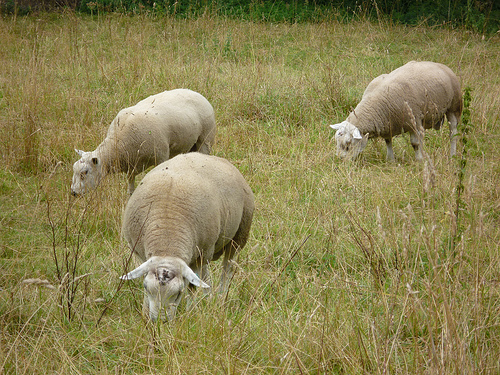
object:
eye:
[81, 170, 88, 179]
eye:
[174, 291, 181, 301]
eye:
[143, 284, 147, 292]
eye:
[344, 146, 350, 151]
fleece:
[142, 172, 206, 257]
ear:
[181, 264, 209, 288]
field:
[0, 0, 500, 375]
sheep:
[118, 151, 255, 325]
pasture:
[0, 15, 500, 375]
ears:
[119, 256, 211, 288]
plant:
[450, 86, 475, 264]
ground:
[0, 11, 500, 375]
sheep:
[68, 60, 463, 324]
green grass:
[0, 0, 500, 33]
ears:
[329, 122, 363, 139]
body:
[107, 88, 208, 144]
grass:
[0, 0, 500, 375]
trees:
[0, 0, 500, 35]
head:
[118, 255, 210, 323]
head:
[70, 148, 101, 197]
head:
[328, 122, 364, 158]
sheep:
[328, 60, 461, 165]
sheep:
[71, 88, 217, 198]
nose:
[149, 315, 167, 327]